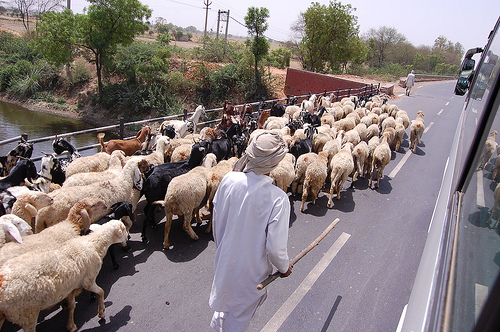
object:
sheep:
[0, 90, 426, 332]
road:
[425, 96, 441, 110]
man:
[215, 127, 291, 329]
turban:
[233, 137, 281, 177]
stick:
[257, 207, 338, 288]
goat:
[137, 145, 217, 226]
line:
[386, 142, 413, 179]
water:
[0, 100, 96, 168]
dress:
[211, 172, 291, 322]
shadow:
[311, 294, 345, 331]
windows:
[434, 127, 498, 330]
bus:
[397, 61, 496, 331]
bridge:
[0, 49, 499, 331]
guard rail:
[2, 83, 381, 149]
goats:
[0, 95, 427, 294]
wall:
[284, 64, 386, 111]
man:
[403, 69, 415, 96]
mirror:
[450, 23, 500, 292]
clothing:
[209, 170, 290, 331]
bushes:
[0, 25, 293, 114]